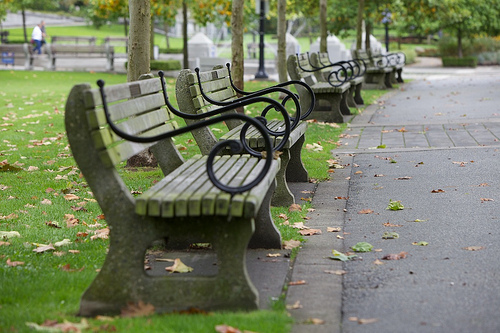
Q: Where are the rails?
A: On bench.